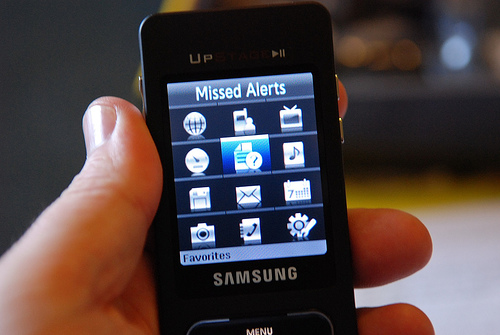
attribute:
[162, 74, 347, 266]
small screen — grey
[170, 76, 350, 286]
phone screen — mobile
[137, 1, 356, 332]
cellphone — black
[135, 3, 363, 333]
phone — small, black, Samsung